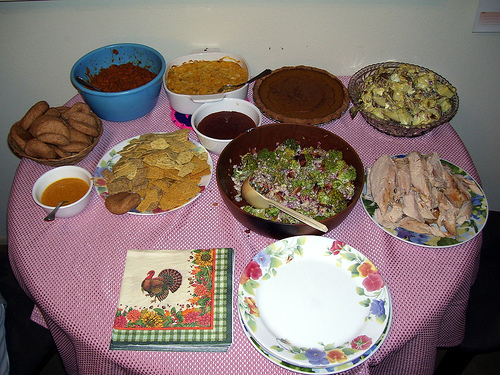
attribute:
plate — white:
[241, 233, 390, 372]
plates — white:
[240, 235, 396, 372]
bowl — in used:
[188, 100, 274, 155]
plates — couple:
[223, 228, 414, 365]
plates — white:
[231, 225, 348, 342]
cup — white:
[33, 161, 94, 218]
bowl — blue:
[63, 33, 167, 123]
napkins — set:
[98, 238, 241, 363]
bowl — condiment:
[34, 167, 95, 218]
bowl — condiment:
[192, 101, 264, 156]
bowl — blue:
[69, 40, 167, 122]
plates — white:
[237, 237, 428, 372]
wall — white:
[5, 3, 498, 62]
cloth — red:
[23, 38, 459, 373]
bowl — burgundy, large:
[215, 120, 364, 240]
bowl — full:
[187, 97, 262, 152]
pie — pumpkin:
[263, 63, 342, 128]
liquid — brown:
[199, 110, 253, 140]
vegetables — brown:
[357, 59, 454, 139]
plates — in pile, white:
[229, 223, 399, 371]